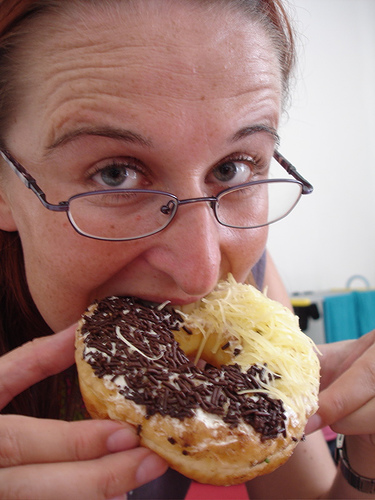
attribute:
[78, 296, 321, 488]
donut — delicious, beautiful, big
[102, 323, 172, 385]
sprinkles — brown, chocolate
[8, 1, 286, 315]
girl — white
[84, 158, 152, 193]
eye — blue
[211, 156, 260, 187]
eye — blue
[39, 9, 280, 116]
forehead — large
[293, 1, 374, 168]
wall — white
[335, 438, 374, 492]
watch — metal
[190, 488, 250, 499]
shirt — red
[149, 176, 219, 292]
nose — big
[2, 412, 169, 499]
fingers — white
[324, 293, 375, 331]
bag — blue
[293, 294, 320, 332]
bag — white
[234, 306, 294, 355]
frosting — coconut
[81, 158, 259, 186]
eyes — blue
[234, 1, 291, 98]
hair — brown, growing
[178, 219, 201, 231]
freckles — red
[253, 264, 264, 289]
cloth — blue